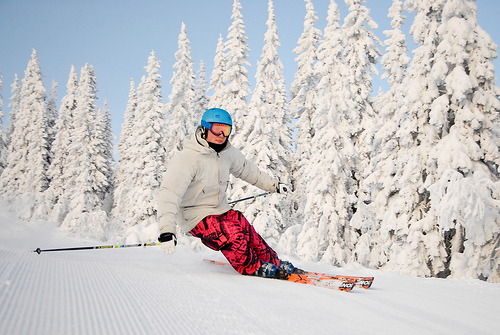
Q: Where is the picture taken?
A: Ski slope.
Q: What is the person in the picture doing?
A: Skiing.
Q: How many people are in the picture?
A: One.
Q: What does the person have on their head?
A: Helmet.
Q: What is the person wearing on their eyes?
A: Goggles.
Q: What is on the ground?
A: Snow.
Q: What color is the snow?
A: White.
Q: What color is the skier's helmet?
A: Blue.